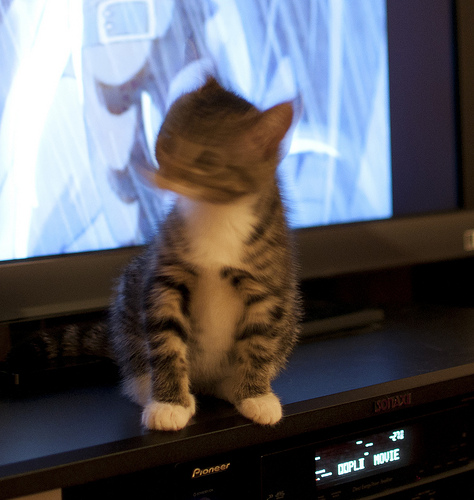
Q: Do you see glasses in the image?
A: No, there are no glasses.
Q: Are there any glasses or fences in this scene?
A: No, there are no glasses or fences.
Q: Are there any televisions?
A: Yes, there is a television.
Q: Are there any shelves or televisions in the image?
A: Yes, there is a television.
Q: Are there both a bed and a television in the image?
A: No, there is a television but no beds.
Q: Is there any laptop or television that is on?
A: Yes, the television is on.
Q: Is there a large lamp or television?
A: Yes, there is a large television.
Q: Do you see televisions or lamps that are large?
A: Yes, the television is large.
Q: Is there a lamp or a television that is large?
A: Yes, the television is large.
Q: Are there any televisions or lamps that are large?
A: Yes, the television is large.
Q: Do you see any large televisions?
A: Yes, there is a large television.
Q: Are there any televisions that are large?
A: Yes, there is a television that is large.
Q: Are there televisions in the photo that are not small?
A: Yes, there is a large television.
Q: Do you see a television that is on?
A: Yes, there is a television that is on.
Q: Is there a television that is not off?
A: Yes, there is a television that is on.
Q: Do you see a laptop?
A: No, there are no laptops.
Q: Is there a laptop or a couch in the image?
A: No, there are no laptops or couches.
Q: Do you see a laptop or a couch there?
A: No, there are no laptops or couches.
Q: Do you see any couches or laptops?
A: No, there are no laptops or couches.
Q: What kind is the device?
A: The device is a television.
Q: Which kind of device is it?
A: The device is a television.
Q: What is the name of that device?
A: This is a television.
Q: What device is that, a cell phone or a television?
A: This is a television.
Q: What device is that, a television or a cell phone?
A: This is a television.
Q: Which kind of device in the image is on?
A: The device is a television.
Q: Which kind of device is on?
A: The device is a television.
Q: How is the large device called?
A: The device is a television.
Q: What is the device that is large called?
A: The device is a television.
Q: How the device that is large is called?
A: The device is a television.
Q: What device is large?
A: The device is a television.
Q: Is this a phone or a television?
A: This is a television.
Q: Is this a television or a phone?
A: This is a television.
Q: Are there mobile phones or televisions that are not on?
A: No, there is a television but it is on.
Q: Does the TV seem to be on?
A: Yes, the TV is on.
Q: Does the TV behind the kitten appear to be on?
A: Yes, the television is on.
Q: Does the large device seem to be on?
A: Yes, the television is on.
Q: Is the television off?
A: No, the television is on.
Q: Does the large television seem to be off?
A: No, the TV is on.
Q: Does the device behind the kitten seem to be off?
A: No, the TV is on.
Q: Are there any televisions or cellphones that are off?
A: No, there is a television but it is on.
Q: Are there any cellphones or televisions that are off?
A: No, there is a television but it is on.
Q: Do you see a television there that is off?
A: No, there is a television but it is on.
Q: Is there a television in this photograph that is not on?
A: No, there is a television but it is on.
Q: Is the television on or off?
A: The television is on.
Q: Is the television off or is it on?
A: The television is on.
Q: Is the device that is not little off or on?
A: The television is on.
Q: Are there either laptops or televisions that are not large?
A: No, there is a television but it is large.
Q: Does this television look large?
A: Yes, the television is large.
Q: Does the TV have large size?
A: Yes, the TV is large.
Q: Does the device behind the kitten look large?
A: Yes, the TV is large.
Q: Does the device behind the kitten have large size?
A: Yes, the TV is large.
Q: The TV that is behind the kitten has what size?
A: The TV is large.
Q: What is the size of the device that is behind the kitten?
A: The TV is large.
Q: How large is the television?
A: The television is large.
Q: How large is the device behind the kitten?
A: The television is large.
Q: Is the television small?
A: No, the television is large.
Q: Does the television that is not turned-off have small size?
A: No, the television is large.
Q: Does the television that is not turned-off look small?
A: No, the television is large.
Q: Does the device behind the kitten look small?
A: No, the television is large.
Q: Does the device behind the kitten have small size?
A: No, the television is large.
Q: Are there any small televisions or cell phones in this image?
A: No, there is a television but it is large.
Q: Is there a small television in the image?
A: No, there is a television but it is large.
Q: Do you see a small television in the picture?
A: No, there is a television but it is large.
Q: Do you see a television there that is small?
A: No, there is a television but it is large.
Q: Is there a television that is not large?
A: No, there is a television but it is large.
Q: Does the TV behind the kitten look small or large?
A: The television is large.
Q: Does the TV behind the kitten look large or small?
A: The television is large.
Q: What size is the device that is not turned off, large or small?
A: The television is large.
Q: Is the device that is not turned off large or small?
A: The television is large.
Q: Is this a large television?
A: Yes, this is a large television.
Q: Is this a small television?
A: No, this is a large television.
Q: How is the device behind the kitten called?
A: The device is a television.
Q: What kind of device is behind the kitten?
A: The device is a television.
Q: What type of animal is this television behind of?
A: The television is behind the kitten.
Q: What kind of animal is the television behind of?
A: The television is behind the kitten.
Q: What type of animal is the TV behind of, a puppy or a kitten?
A: The TV is behind a kitten.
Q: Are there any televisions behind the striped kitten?
A: Yes, there is a television behind the kitten.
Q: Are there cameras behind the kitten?
A: No, there is a television behind the kitten.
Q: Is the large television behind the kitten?
A: Yes, the television is behind the kitten.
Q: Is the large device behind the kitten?
A: Yes, the television is behind the kitten.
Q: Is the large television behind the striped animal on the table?
A: Yes, the television is behind the kitten.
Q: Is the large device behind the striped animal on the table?
A: Yes, the television is behind the kitten.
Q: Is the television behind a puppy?
A: No, the television is behind the kitten.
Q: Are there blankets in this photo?
A: No, there are no blankets.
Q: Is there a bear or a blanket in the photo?
A: No, there are no blankets or bears.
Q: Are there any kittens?
A: Yes, there is a kitten.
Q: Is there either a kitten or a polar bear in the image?
A: Yes, there is a kitten.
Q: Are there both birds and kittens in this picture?
A: No, there is a kitten but no birds.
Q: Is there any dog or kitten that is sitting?
A: Yes, the kitten is sitting.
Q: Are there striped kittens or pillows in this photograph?
A: Yes, there is a striped kitten.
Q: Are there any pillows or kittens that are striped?
A: Yes, the kitten is striped.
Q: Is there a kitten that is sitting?
A: Yes, there is a kitten that is sitting.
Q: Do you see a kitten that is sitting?
A: Yes, there is a kitten that is sitting.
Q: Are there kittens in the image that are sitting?
A: Yes, there is a kitten that is sitting.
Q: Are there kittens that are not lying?
A: Yes, there is a kitten that is sitting.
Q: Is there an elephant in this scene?
A: No, there are no elephants.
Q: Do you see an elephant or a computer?
A: No, there are no elephants or computers.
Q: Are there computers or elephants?
A: No, there are no elephants or computers.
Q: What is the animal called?
A: The animal is a kitten.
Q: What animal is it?
A: The animal is a kitten.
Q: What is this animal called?
A: This is a kitten.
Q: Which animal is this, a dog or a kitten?
A: This is a kitten.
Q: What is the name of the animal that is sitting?
A: The animal is a kitten.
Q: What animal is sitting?
A: The animal is a kitten.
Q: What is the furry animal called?
A: The animal is a kitten.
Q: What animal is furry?
A: The animal is a kitten.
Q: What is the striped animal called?
A: The animal is a kitten.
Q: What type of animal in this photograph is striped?
A: The animal is a kitten.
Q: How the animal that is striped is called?
A: The animal is a kitten.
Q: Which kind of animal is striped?
A: The animal is a kitten.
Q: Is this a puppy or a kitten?
A: This is a kitten.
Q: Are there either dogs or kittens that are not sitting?
A: No, there is a kitten but it is sitting.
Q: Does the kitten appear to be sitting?
A: Yes, the kitten is sitting.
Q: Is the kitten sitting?
A: Yes, the kitten is sitting.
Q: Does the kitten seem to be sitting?
A: Yes, the kitten is sitting.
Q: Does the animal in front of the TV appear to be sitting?
A: Yes, the kitten is sitting.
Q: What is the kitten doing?
A: The kitten is sitting.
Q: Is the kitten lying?
A: No, the kitten is sitting.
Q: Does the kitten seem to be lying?
A: No, the kitten is sitting.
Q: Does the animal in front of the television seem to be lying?
A: No, the kitten is sitting.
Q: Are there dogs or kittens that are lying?
A: No, there is a kitten but it is sitting.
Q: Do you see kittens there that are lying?
A: No, there is a kitten but it is sitting.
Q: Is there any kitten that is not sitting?
A: No, there is a kitten but it is sitting.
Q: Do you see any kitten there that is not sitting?
A: No, there is a kitten but it is sitting.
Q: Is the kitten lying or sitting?
A: The kitten is sitting.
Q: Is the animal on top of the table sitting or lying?
A: The kitten is sitting.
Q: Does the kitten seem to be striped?
A: Yes, the kitten is striped.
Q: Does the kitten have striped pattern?
A: Yes, the kitten is striped.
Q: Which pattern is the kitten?
A: The kitten is striped.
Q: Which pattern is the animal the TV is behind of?
A: The kitten is striped.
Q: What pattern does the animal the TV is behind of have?
A: The kitten has striped pattern.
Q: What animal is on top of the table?
A: The kitten is on top of the table.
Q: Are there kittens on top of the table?
A: Yes, there is a kitten on top of the table.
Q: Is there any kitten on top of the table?
A: Yes, there is a kitten on top of the table.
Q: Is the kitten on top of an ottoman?
A: No, the kitten is on top of the table.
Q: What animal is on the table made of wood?
A: The kitten is on the table.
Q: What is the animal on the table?
A: The animal is a kitten.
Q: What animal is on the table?
A: The animal is a kitten.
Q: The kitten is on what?
A: The kitten is on the table.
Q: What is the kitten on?
A: The kitten is on the table.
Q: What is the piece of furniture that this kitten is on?
A: The piece of furniture is a table.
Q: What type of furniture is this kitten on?
A: The kitten is on the table.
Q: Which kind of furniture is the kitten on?
A: The kitten is on the table.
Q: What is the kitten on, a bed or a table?
A: The kitten is on a table.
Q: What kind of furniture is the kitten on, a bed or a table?
A: The kitten is on a table.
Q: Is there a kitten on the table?
A: Yes, there is a kitten on the table.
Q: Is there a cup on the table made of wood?
A: No, there is a kitten on the table.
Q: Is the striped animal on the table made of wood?
A: Yes, the kitten is on the table.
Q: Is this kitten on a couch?
A: No, the kitten is on the table.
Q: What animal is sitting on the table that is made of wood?
A: The kitten is sitting on the table.